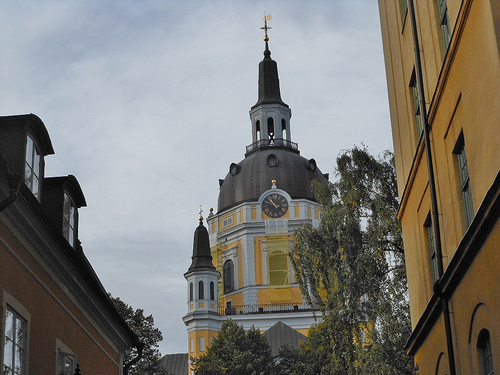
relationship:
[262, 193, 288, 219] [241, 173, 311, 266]
black clock on top of wall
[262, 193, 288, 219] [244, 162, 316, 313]
black clock on top of wall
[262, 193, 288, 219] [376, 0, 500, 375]
black clock on top of building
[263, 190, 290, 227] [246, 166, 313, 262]
black clock on top of wall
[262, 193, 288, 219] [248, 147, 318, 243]
black clock on top of wall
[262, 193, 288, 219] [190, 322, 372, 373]
black clock on top of wall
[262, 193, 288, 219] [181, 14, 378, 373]
black clock on building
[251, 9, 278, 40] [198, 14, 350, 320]
cross on top of bell tower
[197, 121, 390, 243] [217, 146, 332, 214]
dome on dome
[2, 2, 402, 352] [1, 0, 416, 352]
clouds covering sky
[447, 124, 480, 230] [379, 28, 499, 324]
window in building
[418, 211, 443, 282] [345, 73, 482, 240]
window in building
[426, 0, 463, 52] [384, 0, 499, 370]
window in building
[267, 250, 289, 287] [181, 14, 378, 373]
window in building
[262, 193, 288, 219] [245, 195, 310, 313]
black clock on top of wall